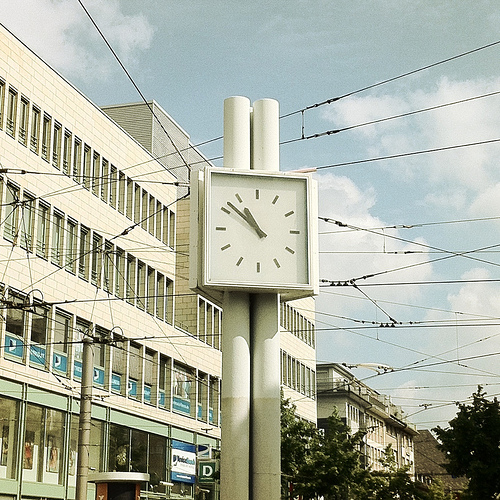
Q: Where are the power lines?
A: Above the clock.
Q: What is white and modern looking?
A: The clock.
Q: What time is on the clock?
A: 10:52.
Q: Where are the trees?
A: Behind the clock.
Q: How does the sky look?
A: Partly cloudy.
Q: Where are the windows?
A: On the building.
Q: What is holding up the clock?
A: Two white poles.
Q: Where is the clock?
A: On the poles.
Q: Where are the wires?
A: In the sky.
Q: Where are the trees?
A: In front of the building.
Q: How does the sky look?
A: Blue with white clouds.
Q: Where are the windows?
A: On the building.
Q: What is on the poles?
A: A clock.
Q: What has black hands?
A: The clock.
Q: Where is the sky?
A: Above the buildings.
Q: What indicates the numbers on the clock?
A: Small dashes.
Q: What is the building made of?
A: White bricks.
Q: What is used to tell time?
A: Clock.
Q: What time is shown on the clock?
A: 10:52.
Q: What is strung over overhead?
A: Utility lines.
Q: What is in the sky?
A: Clouds.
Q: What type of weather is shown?
A: Partly cloudy.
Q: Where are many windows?
A: Buildings.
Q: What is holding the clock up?
A: Posts.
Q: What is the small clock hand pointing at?
A: 11.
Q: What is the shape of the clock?
A: Square.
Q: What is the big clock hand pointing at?
A: 12.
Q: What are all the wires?
A: Electrical wires.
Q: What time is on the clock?
A: 10:52.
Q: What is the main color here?
A: White.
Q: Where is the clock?
A: In the center.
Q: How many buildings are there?
A: Two.